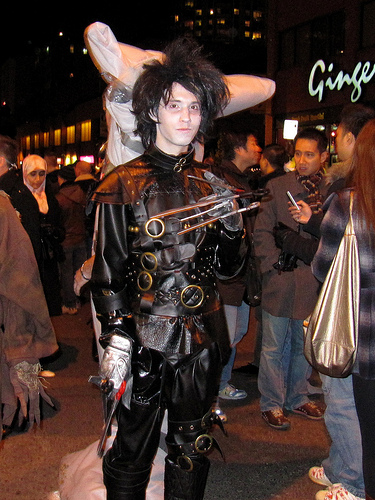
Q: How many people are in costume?
A: One.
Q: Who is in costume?
A: The man.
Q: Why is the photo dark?
A: It is nighttime.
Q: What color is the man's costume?
A: Black.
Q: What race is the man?
A: Caucasian.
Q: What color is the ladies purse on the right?
A: Gold.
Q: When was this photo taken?
A: Night time.